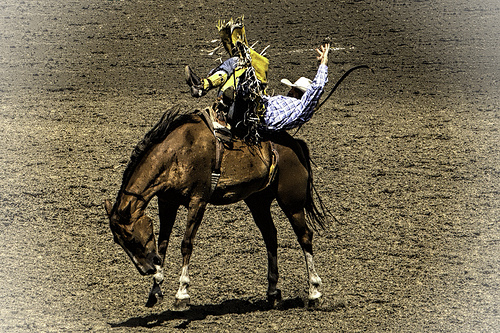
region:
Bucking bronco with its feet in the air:
[103, 107, 344, 314]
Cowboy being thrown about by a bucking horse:
[182, 14, 330, 135]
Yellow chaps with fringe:
[197, 14, 271, 133]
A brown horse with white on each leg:
[100, 105, 340, 315]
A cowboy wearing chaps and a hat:
[185, 14, 332, 129]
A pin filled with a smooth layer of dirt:
[331, 0, 498, 328]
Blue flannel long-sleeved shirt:
[265, 62, 331, 134]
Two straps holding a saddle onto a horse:
[205, 125, 278, 200]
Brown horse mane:
[115, 103, 197, 208]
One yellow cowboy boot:
[180, 63, 226, 99]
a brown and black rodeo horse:
[107, 110, 338, 308]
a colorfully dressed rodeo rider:
[182, 15, 329, 131]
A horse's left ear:
[115, 197, 130, 217]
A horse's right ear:
[99, 200, 113, 219]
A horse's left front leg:
[174, 192, 209, 308]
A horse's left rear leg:
[273, 180, 323, 307]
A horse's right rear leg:
[242, 199, 280, 307]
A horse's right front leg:
[143, 190, 180, 308]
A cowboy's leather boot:
[183, 67, 225, 95]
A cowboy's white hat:
[278, 76, 317, 96]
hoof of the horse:
[305, 269, 335, 309]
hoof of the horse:
[250, 273, 287, 310]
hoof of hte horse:
[173, 284, 213, 311]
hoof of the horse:
[143, 288, 169, 313]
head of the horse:
[100, 199, 161, 277]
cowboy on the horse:
[166, 1, 340, 131]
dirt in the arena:
[363, 270, 403, 307]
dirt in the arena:
[424, 295, 464, 322]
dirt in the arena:
[53, 260, 101, 299]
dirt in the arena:
[366, 190, 413, 221]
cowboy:
[162, 16, 397, 151]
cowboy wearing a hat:
[174, 9, 368, 149]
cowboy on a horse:
[110, 20, 380, 300]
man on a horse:
[97, 10, 372, 320]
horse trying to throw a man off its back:
[115, 15, 375, 315]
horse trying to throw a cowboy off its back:
[102, 10, 382, 317]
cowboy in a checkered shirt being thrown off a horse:
[101, 9, 371, 331]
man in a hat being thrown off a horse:
[111, 11, 373, 317]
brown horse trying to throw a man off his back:
[100, 21, 350, 326]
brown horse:
[97, 112, 337, 324]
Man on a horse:
[93, 47, 364, 316]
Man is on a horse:
[103, 10, 377, 318]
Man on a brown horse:
[101, 15, 375, 318]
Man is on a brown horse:
[113, 10, 375, 314]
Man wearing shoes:
[184, 44, 241, 113]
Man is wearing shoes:
[179, 57, 249, 114]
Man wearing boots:
[180, 60, 242, 115]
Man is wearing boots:
[180, 57, 238, 115]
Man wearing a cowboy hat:
[279, 71, 321, 91]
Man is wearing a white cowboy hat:
[277, 68, 315, 97]